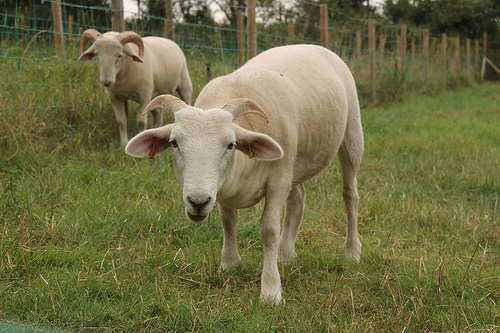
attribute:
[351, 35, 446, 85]
fence — metal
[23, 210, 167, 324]
grass — green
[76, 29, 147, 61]
horns — curved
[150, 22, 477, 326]
sheep — white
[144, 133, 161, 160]
tag — orange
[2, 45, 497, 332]
field — grassy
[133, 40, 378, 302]
sheep — white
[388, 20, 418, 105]
fence post — wooden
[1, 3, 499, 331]
grass — green